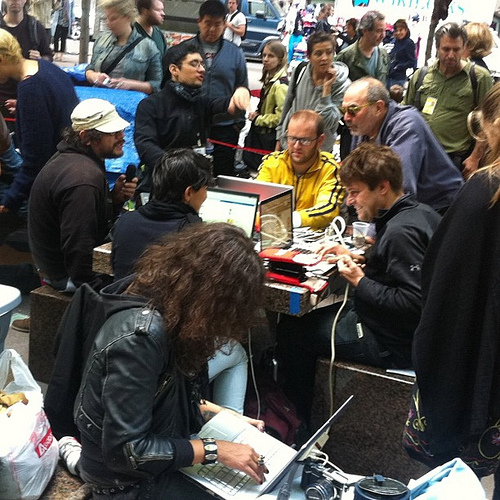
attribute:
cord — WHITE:
[256, 215, 350, 421]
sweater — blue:
[0, 57, 79, 224]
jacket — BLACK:
[378, 226, 406, 250]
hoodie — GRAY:
[285, 56, 369, 156]